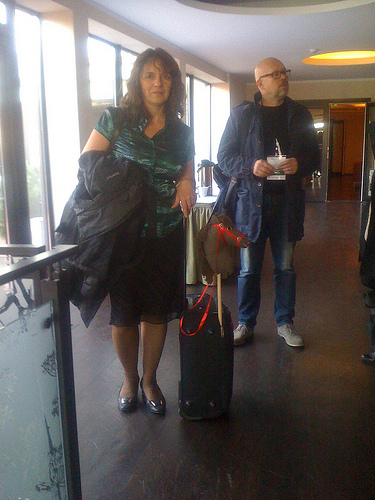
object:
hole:
[176, 0, 372, 16]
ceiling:
[87, 0, 374, 83]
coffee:
[197, 159, 216, 198]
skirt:
[109, 219, 187, 328]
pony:
[179, 212, 251, 337]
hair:
[120, 47, 185, 127]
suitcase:
[178, 268, 234, 421]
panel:
[14, 8, 48, 247]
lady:
[54, 47, 196, 416]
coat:
[53, 150, 148, 330]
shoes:
[117, 375, 166, 414]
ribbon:
[180, 221, 245, 336]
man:
[217, 57, 321, 346]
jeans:
[238, 191, 297, 329]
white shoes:
[233, 324, 304, 347]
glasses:
[257, 70, 291, 83]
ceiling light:
[301, 50, 375, 66]